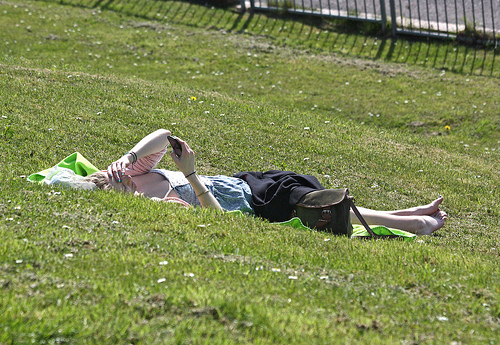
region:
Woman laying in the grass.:
[48, 101, 489, 307]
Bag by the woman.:
[290, 155, 362, 270]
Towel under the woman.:
[37, 125, 212, 242]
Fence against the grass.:
[214, 10, 496, 125]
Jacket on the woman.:
[217, 153, 355, 246]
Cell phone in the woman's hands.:
[167, 135, 193, 167]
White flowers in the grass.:
[40, 191, 265, 334]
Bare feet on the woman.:
[385, 181, 485, 255]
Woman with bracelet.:
[61, 123, 211, 203]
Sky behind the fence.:
[344, 8, 471, 70]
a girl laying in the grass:
[85, 128, 448, 234]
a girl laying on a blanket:
[31, 129, 447, 241]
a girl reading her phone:
[87, 128, 451, 233]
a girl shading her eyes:
[88, 125, 447, 232]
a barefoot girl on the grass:
[91, 127, 451, 235]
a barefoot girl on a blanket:
[87, 123, 448, 240]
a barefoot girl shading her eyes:
[88, 128, 450, 235]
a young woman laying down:
[87, 129, 453, 237]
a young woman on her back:
[90, 128, 447, 242]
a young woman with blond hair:
[92, 127, 444, 233]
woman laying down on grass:
[15, 85, 460, 276]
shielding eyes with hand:
[65, 140, 155, 207]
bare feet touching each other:
[376, 185, 476, 245]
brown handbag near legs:
[271, 155, 391, 250]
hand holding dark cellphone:
[147, 106, 222, 212]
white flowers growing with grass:
[82, 36, 322, 121]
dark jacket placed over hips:
[210, 120, 341, 230]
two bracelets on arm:
[170, 157, 230, 202]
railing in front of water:
[255, 1, 492, 71]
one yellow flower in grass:
[146, 66, 226, 116]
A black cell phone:
[160, 133, 186, 160]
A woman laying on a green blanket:
[28, 125, 453, 250]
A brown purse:
[282, 179, 367, 242]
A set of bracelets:
[122, 147, 142, 162]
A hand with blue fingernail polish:
[100, 149, 143, 186]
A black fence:
[240, 1, 498, 43]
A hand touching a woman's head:
[76, 143, 168, 203]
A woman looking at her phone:
[77, 114, 242, 226]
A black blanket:
[230, 159, 327, 216]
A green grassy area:
[7, 5, 495, 342]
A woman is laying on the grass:
[68, 105, 472, 295]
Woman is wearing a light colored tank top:
[141, 143, 257, 224]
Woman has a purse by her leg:
[291, 180, 377, 247]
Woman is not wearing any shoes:
[393, 183, 465, 253]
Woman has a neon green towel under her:
[20, 136, 462, 278]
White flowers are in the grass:
[22, 198, 354, 335]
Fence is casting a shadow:
[156, 8, 498, 108]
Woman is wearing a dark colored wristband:
[109, 134, 144, 167]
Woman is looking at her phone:
[65, 127, 198, 214]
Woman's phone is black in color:
[157, 125, 201, 175]